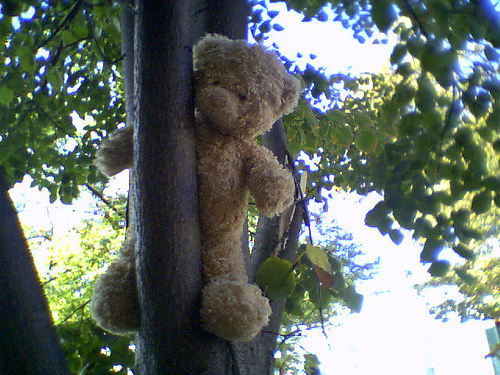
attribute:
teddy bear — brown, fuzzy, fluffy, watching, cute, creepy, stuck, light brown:
[86, 29, 317, 350]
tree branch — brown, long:
[128, 3, 235, 373]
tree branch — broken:
[241, 100, 319, 371]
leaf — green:
[253, 255, 301, 302]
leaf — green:
[357, 130, 377, 152]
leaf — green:
[428, 260, 450, 279]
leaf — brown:
[308, 265, 336, 292]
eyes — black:
[204, 74, 253, 106]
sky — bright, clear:
[13, 12, 486, 373]